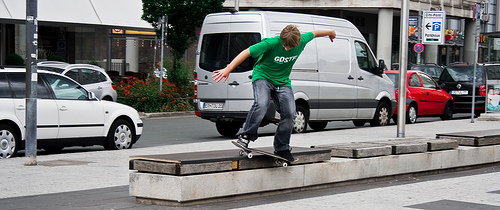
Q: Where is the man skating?
A: On the street.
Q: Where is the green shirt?
A: On the skater.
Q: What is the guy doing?
A: Skateboarding.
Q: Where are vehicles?
A: On the road.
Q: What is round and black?
A: Tires.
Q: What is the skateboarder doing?
A: Performing a trick.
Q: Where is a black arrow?
A: On a sign.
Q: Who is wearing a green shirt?
A: Skateboarder.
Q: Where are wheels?
A: Under the skateboard.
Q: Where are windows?
A: On the vehicles.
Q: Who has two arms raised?
A: The skateboarder.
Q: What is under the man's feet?
A: Skateboard.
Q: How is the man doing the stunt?
A: Jumping.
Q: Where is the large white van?
A: Behind the skateboarder.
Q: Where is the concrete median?
A: Under the skateboarder.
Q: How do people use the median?
A: Like a bench.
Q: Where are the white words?
A: On the green shirt.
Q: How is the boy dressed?
A: Shirt and jeans.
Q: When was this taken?
A: Daytime.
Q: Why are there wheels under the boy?
A: Skateboarding.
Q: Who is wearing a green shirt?
A: Boy.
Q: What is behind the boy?
A: Van.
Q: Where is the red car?
A: On the right.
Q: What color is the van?
A: White.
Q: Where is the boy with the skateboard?
A: Bench.